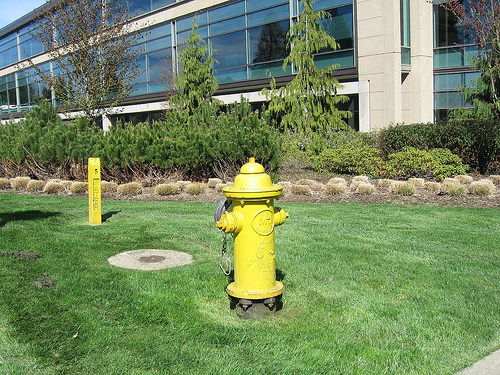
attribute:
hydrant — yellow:
[211, 153, 290, 317]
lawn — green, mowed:
[1, 185, 500, 374]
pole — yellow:
[84, 152, 108, 228]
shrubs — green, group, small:
[2, 97, 279, 183]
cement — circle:
[105, 246, 196, 274]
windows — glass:
[172, 3, 355, 95]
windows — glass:
[47, 19, 177, 108]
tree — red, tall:
[8, 1, 159, 138]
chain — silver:
[218, 230, 235, 276]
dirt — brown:
[276, 168, 361, 186]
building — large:
[2, 2, 495, 140]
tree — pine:
[256, 2, 356, 136]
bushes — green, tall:
[363, 147, 466, 181]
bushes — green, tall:
[312, 144, 384, 170]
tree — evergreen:
[162, 11, 222, 133]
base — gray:
[230, 298, 282, 323]